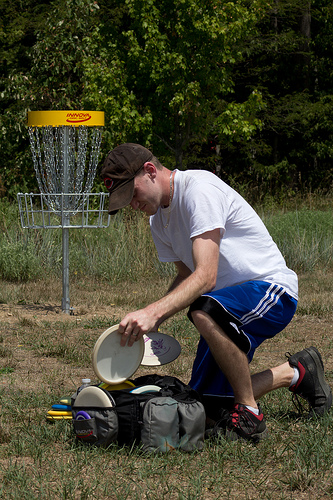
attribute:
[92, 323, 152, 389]
frisbee — white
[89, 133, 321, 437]
man — kneeling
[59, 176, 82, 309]
pole — metal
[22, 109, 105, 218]
device — metal, silver, yellow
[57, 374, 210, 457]
bag — black, gray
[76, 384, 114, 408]
frisbees — stack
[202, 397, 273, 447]
shoe — black, red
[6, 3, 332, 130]
trees — bushy, tall, green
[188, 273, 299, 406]
shorts — blue, white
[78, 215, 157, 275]
grass — tall, green, brown'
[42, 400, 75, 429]
frisbees — yellow, blue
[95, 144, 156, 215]
hat — brown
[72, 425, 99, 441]
logo — innova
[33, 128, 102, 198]
chains — metal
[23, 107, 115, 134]
disk catcher — metal, yellow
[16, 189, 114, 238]
basket — metal, portable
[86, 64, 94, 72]
leaf — green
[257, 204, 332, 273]
grass — green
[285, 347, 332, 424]
shoe — black, red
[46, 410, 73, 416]
frisbee — yellow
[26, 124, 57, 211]
chain — silver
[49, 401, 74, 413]
frisbee — blue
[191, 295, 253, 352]
trim — black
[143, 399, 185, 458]
pouch — gray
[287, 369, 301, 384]
socks — short, white